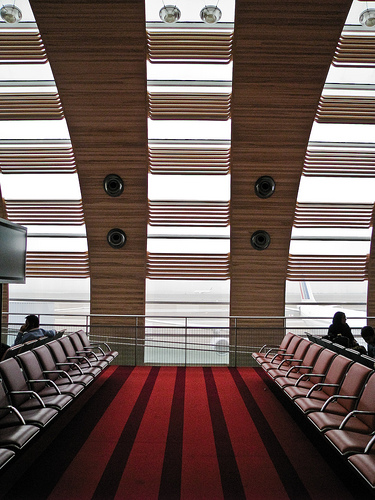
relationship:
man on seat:
[9, 306, 60, 365] [249, 339, 373, 439]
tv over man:
[0, 236, 36, 279] [15, 302, 78, 359]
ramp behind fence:
[148, 309, 227, 360] [60, 308, 295, 374]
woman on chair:
[327, 311, 365, 358] [318, 319, 371, 366]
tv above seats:
[0, 218, 27, 285] [0, 329, 118, 467]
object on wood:
[105, 226, 126, 250] [26, 0, 149, 366]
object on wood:
[254, 177, 275, 196] [231, 0, 357, 366]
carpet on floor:
[0, 0, 375, 499] [11, 350, 373, 498]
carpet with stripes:
[8, 363, 364, 498] [29, 358, 330, 498]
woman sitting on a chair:
[323, 309, 352, 350] [321, 336, 372, 360]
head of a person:
[15, 301, 43, 334] [11, 318, 43, 349]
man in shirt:
[0, 313, 54, 354] [16, 327, 63, 343]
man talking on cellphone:
[0, 313, 54, 354] [26, 323, 32, 332]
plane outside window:
[281, 286, 345, 333] [136, 265, 247, 359]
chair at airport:
[252, 331, 375, 493] [1, 1, 371, 496]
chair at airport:
[0, 329, 119, 473] [1, 1, 371, 496]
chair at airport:
[31, 343, 94, 386] [1, 1, 371, 496]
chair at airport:
[290, 357, 372, 428] [1, 1, 371, 496]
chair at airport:
[252, 331, 375, 493] [29, 217, 316, 473]